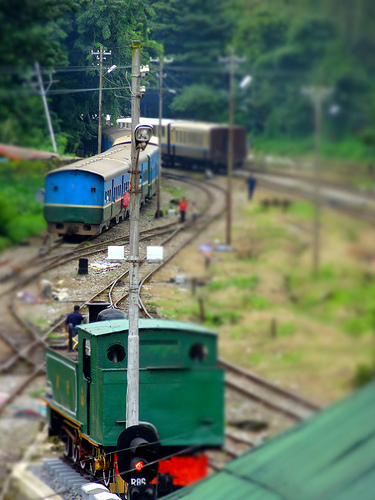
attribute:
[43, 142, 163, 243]
train car — parked, blue, green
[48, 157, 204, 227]
train — blue 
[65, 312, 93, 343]
shirt — blue 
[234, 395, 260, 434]
trees — green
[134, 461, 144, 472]
light — on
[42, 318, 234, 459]
tracks — green 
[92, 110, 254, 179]
train — brown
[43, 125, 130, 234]
train — long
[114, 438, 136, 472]
plate — black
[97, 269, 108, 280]
rock — gray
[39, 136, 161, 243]
train — blue 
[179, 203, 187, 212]
shirt — red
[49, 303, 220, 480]
cab — red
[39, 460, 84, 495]
plates — silver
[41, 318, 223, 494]
cab — green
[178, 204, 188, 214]
shirt — red